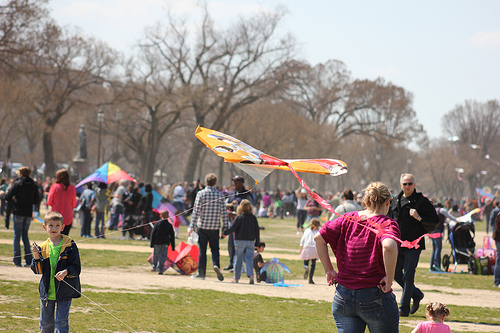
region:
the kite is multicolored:
[190, 89, 454, 263]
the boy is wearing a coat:
[17, 234, 138, 291]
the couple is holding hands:
[199, 197, 284, 276]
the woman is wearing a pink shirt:
[307, 206, 488, 307]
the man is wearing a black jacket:
[373, 192, 498, 284]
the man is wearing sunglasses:
[392, 164, 422, 206]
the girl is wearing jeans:
[228, 228, 293, 299]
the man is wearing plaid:
[181, 180, 230, 232]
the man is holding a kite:
[165, 220, 245, 314]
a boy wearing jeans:
[26, 210, 83, 332]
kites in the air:
[445, 139, 499, 184]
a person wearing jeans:
[3, 163, 41, 271]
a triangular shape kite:
[72, 157, 138, 191]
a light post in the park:
[92, 105, 109, 165]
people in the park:
[1, 114, 498, 331]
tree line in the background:
[2, 0, 499, 162]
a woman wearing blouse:
[42, 165, 79, 227]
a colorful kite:
[68, 156, 143, 194]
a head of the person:
[203, 172, 218, 186]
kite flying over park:
[195, 124, 325, 177]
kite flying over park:
[82, 160, 124, 188]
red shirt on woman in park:
[317, 196, 398, 288]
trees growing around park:
[27, 20, 498, 200]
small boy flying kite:
[32, 208, 83, 331]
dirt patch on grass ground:
[100, 242, 367, 287]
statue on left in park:
[75, 119, 91, 167]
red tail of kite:
[299, 181, 441, 254]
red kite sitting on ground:
[152, 234, 202, 279]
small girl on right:
[417, 306, 445, 328]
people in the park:
[2, 120, 499, 331]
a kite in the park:
[188, 119, 352, 196]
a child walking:
[406, 300, 454, 332]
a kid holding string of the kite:
[28, 210, 143, 331]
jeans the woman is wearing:
[228, 238, 259, 278]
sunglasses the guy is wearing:
[399, 180, 414, 187]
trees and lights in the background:
[2, 1, 499, 163]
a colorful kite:
[71, 159, 138, 189]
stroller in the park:
[438, 210, 480, 275]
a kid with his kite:
[251, 240, 293, 287]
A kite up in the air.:
[180, 122, 356, 202]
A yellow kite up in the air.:
[192, 123, 440, 264]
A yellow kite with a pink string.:
[190, 121, 441, 275]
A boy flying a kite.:
[8, 211, 91, 331]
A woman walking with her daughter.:
[313, 181, 463, 331]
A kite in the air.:
[73, 156, 138, 201]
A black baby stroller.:
[440, 212, 485, 285]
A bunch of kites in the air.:
[438, 131, 498, 200]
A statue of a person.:
[65, 123, 95, 181]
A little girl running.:
[293, 217, 325, 282]